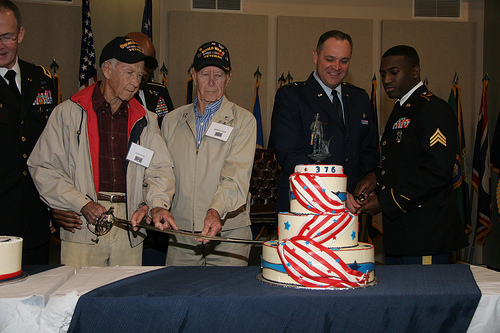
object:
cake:
[262, 164, 375, 291]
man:
[131, 41, 257, 277]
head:
[191, 43, 233, 102]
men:
[26, 36, 265, 268]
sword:
[84, 206, 266, 245]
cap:
[193, 41, 231, 74]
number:
[314, 166, 336, 174]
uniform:
[160, 95, 257, 266]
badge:
[205, 121, 235, 142]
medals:
[392, 117, 411, 129]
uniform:
[373, 81, 469, 265]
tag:
[126, 142, 155, 168]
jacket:
[24, 79, 175, 249]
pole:
[252, 65, 264, 148]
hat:
[99, 36, 159, 68]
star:
[283, 221, 291, 230]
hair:
[382, 44, 420, 66]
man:
[1, 0, 61, 263]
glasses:
[0, 34, 14, 42]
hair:
[101, 58, 119, 73]